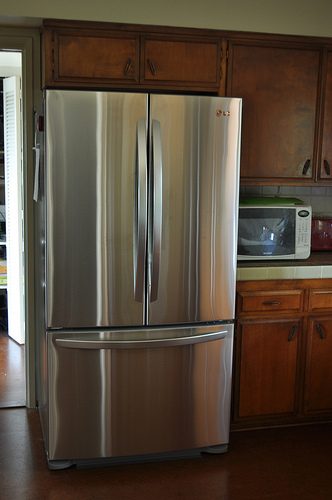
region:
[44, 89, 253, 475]
stainless steel 3 door refrigerator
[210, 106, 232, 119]
brand logo on refrigerator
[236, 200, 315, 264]
microwave oven on counter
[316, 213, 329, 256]
brown cannister on counter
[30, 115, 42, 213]
papers hanging on side of refrigeraor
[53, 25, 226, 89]
small cabinets above refrigerator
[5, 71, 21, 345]
white louver door in other room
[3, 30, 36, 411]
doorway to another room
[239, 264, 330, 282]
white tile counter edging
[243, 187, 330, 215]
white tile backsplash behind microwave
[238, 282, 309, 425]
A wooden kitchen cabin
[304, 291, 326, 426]
A wooden kitchen cabin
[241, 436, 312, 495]
smooth cemented kitchen floor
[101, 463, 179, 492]
smooth cemented kitchen floor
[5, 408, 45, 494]
smooth cemented kitchen floor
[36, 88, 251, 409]
A big silver fridge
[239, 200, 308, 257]
A small microwave machine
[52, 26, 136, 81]
A wooden kitchen cabin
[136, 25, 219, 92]
A wooden kitchen cabin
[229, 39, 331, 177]
A wooden kitchen cabin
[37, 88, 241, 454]
silver fridge with two doors and bottom drawer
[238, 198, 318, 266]
white microwave next to fridge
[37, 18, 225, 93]
two cabinets above fridge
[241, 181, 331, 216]
white tiles on kitchen wall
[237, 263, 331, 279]
countertop that microwave is on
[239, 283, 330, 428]
two floor level cabinets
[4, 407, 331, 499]
brown floor of the kitchen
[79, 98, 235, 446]
reflections on the fridge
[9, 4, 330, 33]
wall above kitchen cabinets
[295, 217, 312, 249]
control panel on microwave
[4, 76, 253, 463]
the refrigerator is silver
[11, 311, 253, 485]
the drawer on the fridge is big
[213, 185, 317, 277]
the microwave is on the counter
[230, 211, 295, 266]
reflection in the microwave door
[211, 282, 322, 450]
the cabinets are brown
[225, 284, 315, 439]
the cabinets are made of wood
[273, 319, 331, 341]
the handles are black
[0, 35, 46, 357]
the door is open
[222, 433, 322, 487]
the floor is brown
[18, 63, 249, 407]
the refrigerator is stainless steel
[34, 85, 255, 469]
a tall metal refrigerator.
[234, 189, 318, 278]
a white microwave oven.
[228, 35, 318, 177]
a large wooden cabinet.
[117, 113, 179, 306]
two metal handles on a refrigerator.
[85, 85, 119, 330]
light reflecting on a refrigerator.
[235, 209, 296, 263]
glass door on a microwave.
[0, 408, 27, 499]
light reflecting on a floor.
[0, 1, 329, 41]
a section of wall in a kitchen.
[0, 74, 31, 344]
an entrance into a kitchen.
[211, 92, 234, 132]
an emblem on a refrigerator.